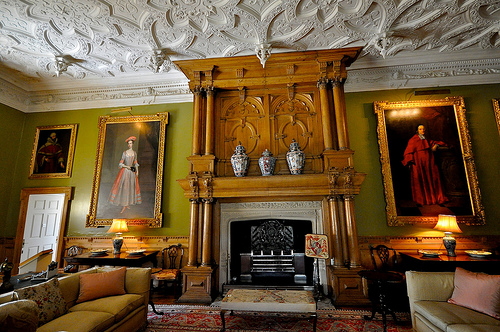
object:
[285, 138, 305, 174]
vase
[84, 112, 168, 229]
painting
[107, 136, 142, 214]
woman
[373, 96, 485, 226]
painting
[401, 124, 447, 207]
man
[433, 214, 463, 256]
lamp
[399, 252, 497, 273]
table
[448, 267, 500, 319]
pillow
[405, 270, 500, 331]
sofa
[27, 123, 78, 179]
painting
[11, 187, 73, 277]
door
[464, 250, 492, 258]
plate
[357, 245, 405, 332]
chair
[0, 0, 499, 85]
ceiling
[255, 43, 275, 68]
spire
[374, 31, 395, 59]
spire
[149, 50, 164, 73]
spire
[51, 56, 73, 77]
spire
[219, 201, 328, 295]
fireplace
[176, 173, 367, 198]
mantle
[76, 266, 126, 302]
pillow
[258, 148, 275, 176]
vase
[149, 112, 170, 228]
frame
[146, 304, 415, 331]
rug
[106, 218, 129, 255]
lamp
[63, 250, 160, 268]
table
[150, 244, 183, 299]
chair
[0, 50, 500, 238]
wall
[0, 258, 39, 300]
pillow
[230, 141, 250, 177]
vase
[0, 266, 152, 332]
sofa